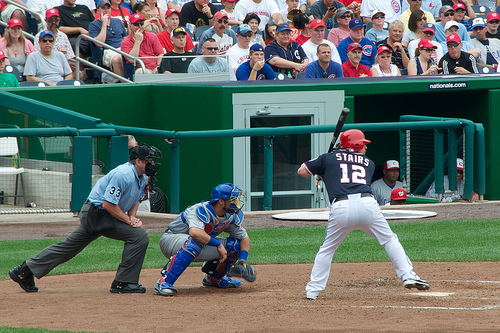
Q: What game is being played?
A: Baseball.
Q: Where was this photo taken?
A: Baseball stadium.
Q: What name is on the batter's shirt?
A: STAIRS.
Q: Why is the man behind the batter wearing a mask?
A: Protection.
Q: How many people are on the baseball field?
A: Three.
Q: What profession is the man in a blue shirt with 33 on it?
A: Umpire.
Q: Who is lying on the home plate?
A: No one.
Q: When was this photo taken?
A: Daytime.